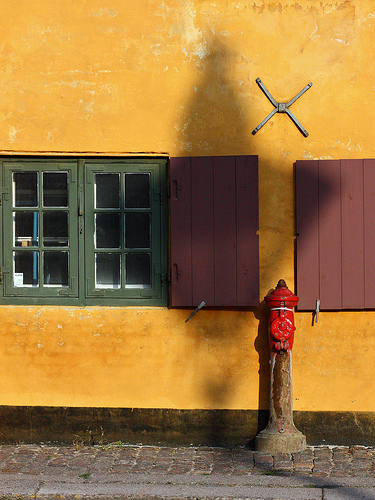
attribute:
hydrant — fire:
[262, 274, 300, 452]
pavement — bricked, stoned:
[0, 442, 373, 493]